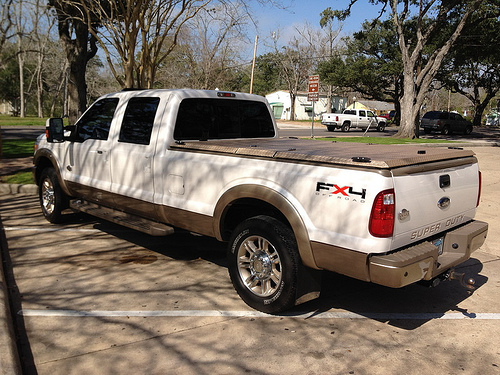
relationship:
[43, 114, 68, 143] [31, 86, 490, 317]
mirror on truck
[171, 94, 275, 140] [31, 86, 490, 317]
window on back of truck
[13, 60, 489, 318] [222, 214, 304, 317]
truck has wheel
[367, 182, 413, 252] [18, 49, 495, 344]
light on truck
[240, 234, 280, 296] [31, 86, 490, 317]
chrome rim on truck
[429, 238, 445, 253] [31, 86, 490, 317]
license plate on truck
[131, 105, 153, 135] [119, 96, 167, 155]
tints on window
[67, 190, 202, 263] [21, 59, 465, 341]
board on truck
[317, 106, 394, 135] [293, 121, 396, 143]
truck on street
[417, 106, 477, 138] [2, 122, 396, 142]
jeep parked on street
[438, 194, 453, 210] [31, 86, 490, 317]
ford emblem on truck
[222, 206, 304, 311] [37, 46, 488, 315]
wheel of truck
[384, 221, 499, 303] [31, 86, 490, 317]
bumper of truck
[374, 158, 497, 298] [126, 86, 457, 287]
rear of truck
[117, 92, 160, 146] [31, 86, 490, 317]
window of truck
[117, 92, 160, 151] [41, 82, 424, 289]
window of truck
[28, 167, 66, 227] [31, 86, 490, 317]
wheel of truck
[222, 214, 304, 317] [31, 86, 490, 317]
wheel of truck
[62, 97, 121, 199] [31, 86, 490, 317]
door of truck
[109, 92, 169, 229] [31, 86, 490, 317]
door of truck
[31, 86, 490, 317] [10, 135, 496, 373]
truck in parking lot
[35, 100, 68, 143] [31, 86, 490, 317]
mirror on truck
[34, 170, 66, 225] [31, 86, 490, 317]
front tire on truck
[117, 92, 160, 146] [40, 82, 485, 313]
window behind diver